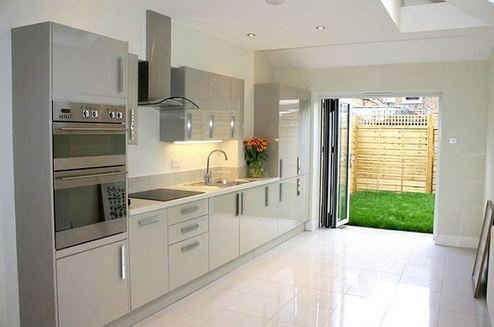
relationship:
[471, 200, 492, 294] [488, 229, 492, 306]
mirror leans on cabinet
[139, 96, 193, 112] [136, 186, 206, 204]
overhead over stove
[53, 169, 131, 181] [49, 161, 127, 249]
handle on stove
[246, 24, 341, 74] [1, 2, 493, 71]
lights on ceiling